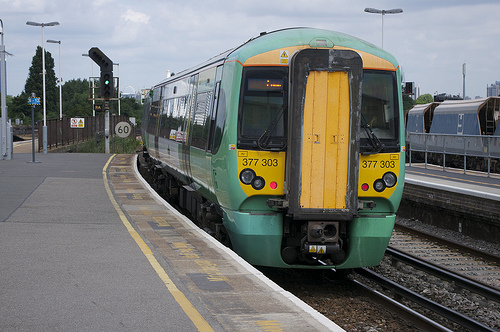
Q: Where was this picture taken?
A: AT the train depot.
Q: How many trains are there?
A: 2.